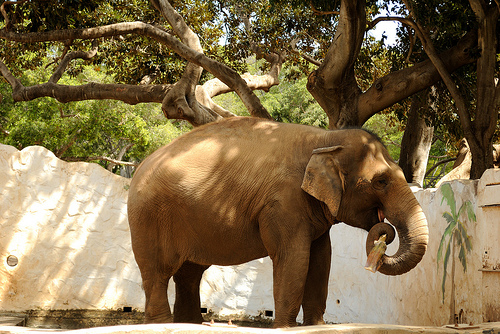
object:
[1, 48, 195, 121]
branch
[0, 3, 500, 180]
tree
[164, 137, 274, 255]
stomach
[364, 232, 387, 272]
branch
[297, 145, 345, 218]
ear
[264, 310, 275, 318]
hole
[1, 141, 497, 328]
barrier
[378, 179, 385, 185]
eye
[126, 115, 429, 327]
elephant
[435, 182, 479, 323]
painting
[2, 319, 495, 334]
floor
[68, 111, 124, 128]
leaves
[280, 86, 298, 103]
leaves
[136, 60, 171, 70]
leaves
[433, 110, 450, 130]
leaves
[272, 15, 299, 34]
leaves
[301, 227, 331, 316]
leg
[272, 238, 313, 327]
leg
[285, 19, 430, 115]
branch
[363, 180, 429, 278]
trunk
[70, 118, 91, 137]
leaves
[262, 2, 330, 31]
leaves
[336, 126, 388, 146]
hair